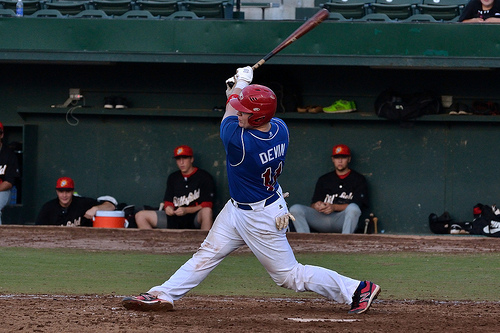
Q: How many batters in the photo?
A: One.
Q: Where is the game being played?
A: Ball field.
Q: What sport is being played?
A: Baseball.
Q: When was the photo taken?
A: Daytime.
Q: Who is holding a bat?
A: The batter.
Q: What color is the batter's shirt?
A: Blue and white.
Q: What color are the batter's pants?
A: White.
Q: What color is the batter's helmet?
A: Red.